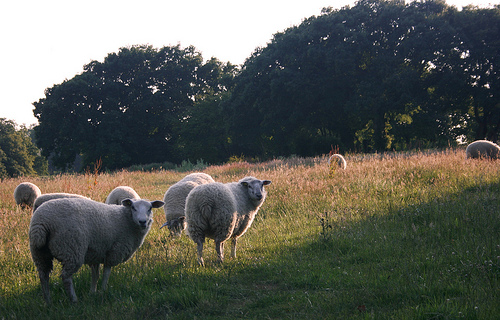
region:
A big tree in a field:
[37, 50, 225, 161]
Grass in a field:
[310, 199, 467, 319]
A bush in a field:
[0, 117, 47, 182]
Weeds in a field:
[281, 164, 340, 201]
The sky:
[8, 0, 258, 40]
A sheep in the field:
[200, 175, 290, 277]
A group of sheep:
[16, 170, 291, 270]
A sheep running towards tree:
[325, 150, 352, 180]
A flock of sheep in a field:
[2, 47, 484, 306]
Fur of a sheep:
[28, 182, 103, 260]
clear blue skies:
[212, 1, 293, 23]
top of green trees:
[55, 44, 242, 80]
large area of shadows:
[313, 215, 435, 280]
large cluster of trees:
[18, 0, 485, 154]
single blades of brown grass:
[281, 143, 311, 184]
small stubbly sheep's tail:
[188, 201, 236, 224]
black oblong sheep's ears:
[120, 181, 165, 215]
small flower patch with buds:
[304, 208, 346, 256]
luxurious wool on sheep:
[194, 177, 234, 202]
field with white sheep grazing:
[17, 139, 482, 280]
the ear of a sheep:
[149, 197, 166, 212]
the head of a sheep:
[121, 195, 167, 231]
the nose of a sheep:
[254, 190, 264, 200]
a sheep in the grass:
[26, 195, 165, 301]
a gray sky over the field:
[1, 0, 499, 147]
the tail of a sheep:
[25, 213, 54, 255]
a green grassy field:
[0, 140, 496, 318]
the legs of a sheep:
[186, 230, 237, 260]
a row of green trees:
[0, 0, 499, 181]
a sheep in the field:
[186, 174, 269, 264]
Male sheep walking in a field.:
[331, 153, 347, 169]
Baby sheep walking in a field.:
[14, 180, 37, 202]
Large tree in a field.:
[33, 47, 240, 170]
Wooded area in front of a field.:
[19, 2, 495, 174]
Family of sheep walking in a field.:
[15, 175, 270, 301]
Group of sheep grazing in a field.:
[2, 170, 275, 294]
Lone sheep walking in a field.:
[328, 152, 345, 170]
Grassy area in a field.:
[323, 186, 485, 317]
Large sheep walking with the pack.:
[186, 176, 266, 260]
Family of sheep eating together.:
[13, 170, 270, 300]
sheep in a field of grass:
[0, 57, 445, 309]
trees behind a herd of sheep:
[34, 33, 378, 209]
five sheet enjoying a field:
[0, 146, 301, 255]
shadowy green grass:
[307, 192, 424, 292]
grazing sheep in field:
[275, 63, 497, 195]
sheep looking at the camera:
[13, 59, 297, 304]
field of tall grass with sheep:
[296, 89, 436, 205]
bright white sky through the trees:
[27, 6, 232, 123]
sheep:
[26, 132, 298, 261]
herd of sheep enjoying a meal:
[15, 7, 456, 274]